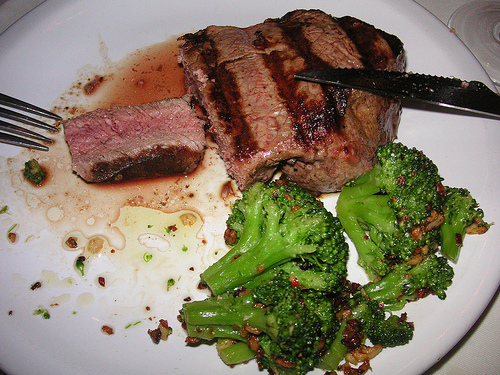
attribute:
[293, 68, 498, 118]
knife — jagged, silver, steel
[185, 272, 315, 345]
vegetable — cooked, steamed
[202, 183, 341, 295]
vegetable — cooked, steamed, green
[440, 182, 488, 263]
vegetable — cooked, small, green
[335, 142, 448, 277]
vegetable — cooked, steamed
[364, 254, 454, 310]
vegetable — cooked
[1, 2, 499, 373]
plate — white, oval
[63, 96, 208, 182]
meat — barbecued, cut out, grilled, medium rare, cut off, rare, small, cut, medium, sliced, brown, pink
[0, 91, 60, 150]
fork — metal, silver, steel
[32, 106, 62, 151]
tips — pointed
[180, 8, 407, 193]
meat — barbecued, grilled, half eaten, brown, pink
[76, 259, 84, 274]
piece of food — scattered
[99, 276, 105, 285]
piece of food — scattered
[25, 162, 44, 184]
piece of food — scattered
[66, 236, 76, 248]
piece of food — scattered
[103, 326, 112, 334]
piece of food — scattered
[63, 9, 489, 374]
meal — partially eaten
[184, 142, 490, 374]
broccoli bunch — green, together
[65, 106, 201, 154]
middle of meat — pink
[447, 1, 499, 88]
glass — Clear